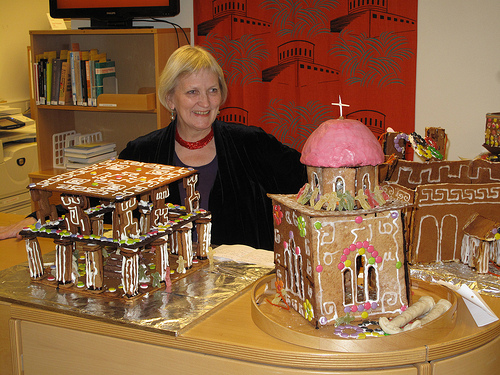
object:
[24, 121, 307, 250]
jacket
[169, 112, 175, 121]
earring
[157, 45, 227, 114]
hair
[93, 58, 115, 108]
books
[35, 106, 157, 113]
shelf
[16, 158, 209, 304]
structure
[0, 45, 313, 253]
woman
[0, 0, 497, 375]
house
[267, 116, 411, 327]
bread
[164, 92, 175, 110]
ear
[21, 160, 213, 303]
cake